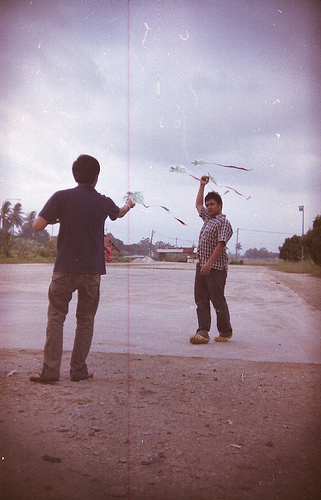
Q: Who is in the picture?
A: Two men are in the picture.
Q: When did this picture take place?
A: It took place in the day time.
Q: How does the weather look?
A: The weather looks cloudy.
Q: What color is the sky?
A: The sky is grey.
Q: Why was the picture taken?
A: To show the two men.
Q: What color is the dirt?
A: The dirt is brown.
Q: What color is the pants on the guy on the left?
A: His pants are brown.